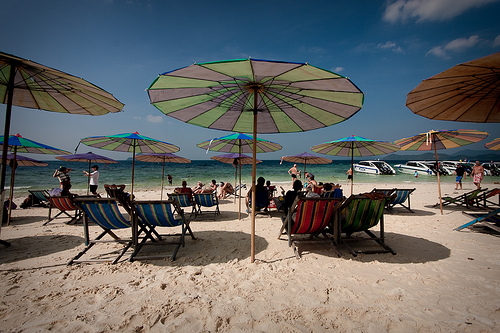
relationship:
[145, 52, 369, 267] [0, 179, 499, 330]
umbrella sticking out of sand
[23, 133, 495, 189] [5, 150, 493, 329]
water near beach.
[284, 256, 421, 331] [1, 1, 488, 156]
beach under sky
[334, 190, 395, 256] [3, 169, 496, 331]
chair on beach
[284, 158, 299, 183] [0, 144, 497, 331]
standing man standing on beach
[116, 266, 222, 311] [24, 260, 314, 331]
foot prints are on sand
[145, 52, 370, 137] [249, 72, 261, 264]
umbrella under pole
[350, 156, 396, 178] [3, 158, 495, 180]
boat in ocean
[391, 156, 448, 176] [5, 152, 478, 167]
boat in ocean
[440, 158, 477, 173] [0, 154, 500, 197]
boat in ocean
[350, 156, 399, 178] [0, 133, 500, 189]
boat in water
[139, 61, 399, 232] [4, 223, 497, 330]
big umbrella stuck in sand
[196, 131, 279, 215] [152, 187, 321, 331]
umbrella stuck in sand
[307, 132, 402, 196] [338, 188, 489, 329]
umbrella stuck in sand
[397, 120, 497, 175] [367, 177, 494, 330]
umbrella stuck in sand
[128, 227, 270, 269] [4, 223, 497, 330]
shadow on sand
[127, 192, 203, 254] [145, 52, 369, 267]
chair next to umbrella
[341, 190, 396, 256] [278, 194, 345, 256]
chair next to chair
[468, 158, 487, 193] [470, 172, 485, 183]
man wearing shorts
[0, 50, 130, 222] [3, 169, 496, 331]
umbrella on beach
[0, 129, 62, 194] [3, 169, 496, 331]
umbrella on beach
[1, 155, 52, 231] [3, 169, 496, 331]
umbrella on beach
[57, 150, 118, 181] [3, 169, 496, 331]
umbrella on beach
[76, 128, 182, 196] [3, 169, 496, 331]
umbrella on beach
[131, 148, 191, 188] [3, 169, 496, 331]
umbrella on beach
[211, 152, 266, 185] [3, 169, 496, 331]
umbrella on beach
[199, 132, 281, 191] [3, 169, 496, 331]
umbrella on beach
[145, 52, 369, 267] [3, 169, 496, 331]
umbrella on beach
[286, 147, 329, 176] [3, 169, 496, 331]
umbrella on beach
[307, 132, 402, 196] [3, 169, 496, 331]
umbrella on beach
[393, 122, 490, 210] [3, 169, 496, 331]
umbrella on beach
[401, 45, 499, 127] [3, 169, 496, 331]
umbrella on beach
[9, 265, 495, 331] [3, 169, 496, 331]
sand on beach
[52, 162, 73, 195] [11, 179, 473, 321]
person on beach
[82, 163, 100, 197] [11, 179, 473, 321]
person on beach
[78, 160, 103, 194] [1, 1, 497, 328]
woman taking picture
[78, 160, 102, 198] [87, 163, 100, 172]
woman wearing cap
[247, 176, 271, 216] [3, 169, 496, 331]
man sitting on beach